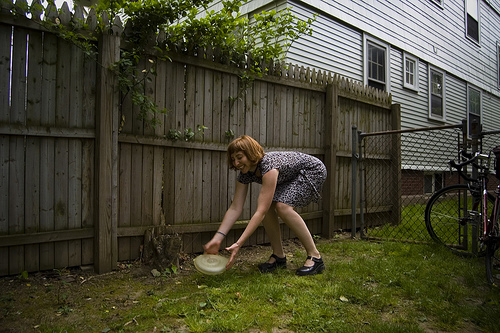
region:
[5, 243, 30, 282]
Small brown plank of wood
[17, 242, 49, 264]
Small brown plank of wood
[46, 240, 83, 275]
Small brown plank of wood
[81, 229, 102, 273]
Small brown plank of wood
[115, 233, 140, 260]
Small brown plank of wood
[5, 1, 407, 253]
Large brown wooden fence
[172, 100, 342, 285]
Woman catching a frisbee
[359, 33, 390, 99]
White window on a house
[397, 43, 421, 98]
White window on a house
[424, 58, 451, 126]
White window on a house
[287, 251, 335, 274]
left foot on woman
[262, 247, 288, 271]
right foot on woman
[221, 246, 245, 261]
left hand on woman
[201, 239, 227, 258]
right hand on woman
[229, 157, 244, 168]
small nose on woman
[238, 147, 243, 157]
left eye on woman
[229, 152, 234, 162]
right eye on woman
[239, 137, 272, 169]
red hair on woman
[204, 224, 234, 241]
black bracelet on woman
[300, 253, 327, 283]
black shoe on woman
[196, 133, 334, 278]
woman bending over to pick up frisbee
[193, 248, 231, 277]
white frisbee between woman's hands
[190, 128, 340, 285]
red haired woman wearing black floral dress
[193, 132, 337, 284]
woman wearing black mary janes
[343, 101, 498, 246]
metal fence gate behind woman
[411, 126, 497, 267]
bike parked against fence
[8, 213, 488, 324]
green grassy back yard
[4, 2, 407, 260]
wooden picket fence surrounding back yard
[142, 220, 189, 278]
camo back pack sitting against fence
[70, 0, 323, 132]
tree grwoing over fence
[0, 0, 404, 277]
wooden fence is brown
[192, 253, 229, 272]
frisbee in the woman's hands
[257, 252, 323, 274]
black bucket shoes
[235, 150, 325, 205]
floral patterned dress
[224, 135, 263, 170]
woman has short red hair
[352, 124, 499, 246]
short metal fence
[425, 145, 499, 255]
a bicycle is leaning on the fence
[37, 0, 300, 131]
green plant growing over the fence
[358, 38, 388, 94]
house window is open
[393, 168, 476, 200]
bottom of the house is brick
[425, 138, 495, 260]
red bike leaned against fence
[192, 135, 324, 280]
woman in dress picking up frisbee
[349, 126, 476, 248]
rusty metal chain link fence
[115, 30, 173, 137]
green vines on wood fence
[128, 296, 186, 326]
green moss on the ground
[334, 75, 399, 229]
wood picket fence by house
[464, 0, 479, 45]
window on second story of the house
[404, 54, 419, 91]
small window with white trim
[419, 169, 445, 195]
basement window with white trim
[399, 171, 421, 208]
red brick foundation of house